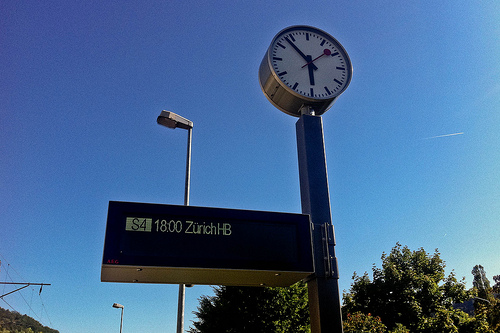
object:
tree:
[340, 241, 471, 332]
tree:
[185, 281, 314, 333]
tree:
[343, 309, 389, 333]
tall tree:
[342, 309, 385, 332]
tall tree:
[461, 266, 499, 333]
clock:
[257, 24, 353, 99]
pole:
[293, 114, 346, 332]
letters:
[223, 223, 233, 235]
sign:
[103, 200, 314, 273]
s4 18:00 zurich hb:
[125, 216, 233, 238]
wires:
[1, 256, 47, 325]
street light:
[156, 109, 195, 129]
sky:
[2, 0, 499, 330]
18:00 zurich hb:
[154, 217, 232, 235]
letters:
[127, 217, 139, 230]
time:
[154, 217, 182, 234]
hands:
[282, 35, 318, 69]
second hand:
[302, 49, 331, 66]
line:
[429, 129, 465, 138]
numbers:
[139, 218, 147, 229]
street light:
[112, 301, 127, 308]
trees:
[0, 308, 59, 333]